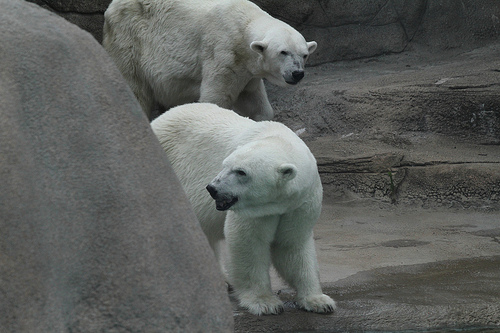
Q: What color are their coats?
A: White.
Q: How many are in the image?
A: Two.